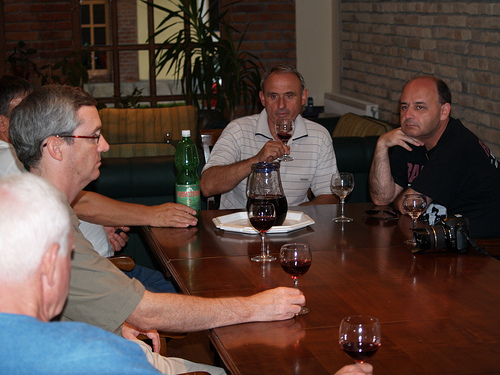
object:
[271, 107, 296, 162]
wine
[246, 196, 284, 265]
glass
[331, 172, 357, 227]
glass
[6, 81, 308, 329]
man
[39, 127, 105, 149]
glasses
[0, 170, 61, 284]
white hair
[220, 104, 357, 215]
shirt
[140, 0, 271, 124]
plant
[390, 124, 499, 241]
shirt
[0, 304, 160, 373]
shirt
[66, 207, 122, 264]
shirt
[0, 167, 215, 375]
man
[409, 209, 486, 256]
camera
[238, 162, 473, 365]
multiple glasses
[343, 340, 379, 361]
wine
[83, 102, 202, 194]
couch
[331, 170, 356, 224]
wine glass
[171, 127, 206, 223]
bottle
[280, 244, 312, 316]
glass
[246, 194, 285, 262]
wine glasses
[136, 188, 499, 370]
brown table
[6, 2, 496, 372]
restaurant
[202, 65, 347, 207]
man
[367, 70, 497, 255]
man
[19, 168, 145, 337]
shirt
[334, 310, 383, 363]
glass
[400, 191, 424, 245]
glass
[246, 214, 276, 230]
wine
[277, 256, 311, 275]
wine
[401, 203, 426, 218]
wine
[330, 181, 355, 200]
wine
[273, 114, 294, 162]
glass